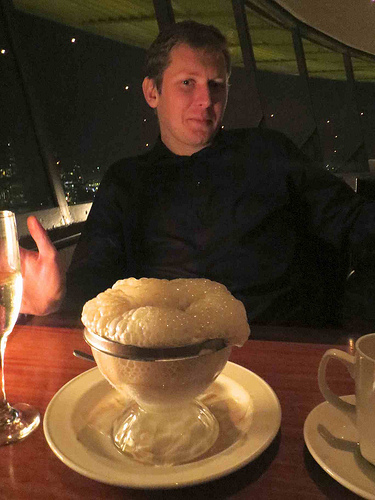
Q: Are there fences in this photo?
A: No, there are no fences.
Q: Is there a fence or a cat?
A: No, there are no fences or cats.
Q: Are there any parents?
A: No, there are no parents.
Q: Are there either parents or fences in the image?
A: No, there are no parents or fences.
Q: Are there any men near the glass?
A: Yes, there is a man near the glass.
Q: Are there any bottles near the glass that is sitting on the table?
A: No, there is a man near the glass.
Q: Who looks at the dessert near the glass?
A: The man looks at the dessert.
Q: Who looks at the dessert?
A: The man looks at the dessert.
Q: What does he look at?
A: The man looks at the dessert.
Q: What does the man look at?
A: The man looks at the dessert.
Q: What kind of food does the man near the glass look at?
A: The man looks at the dessert.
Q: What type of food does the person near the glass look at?
A: The man looks at the dessert.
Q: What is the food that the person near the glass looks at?
A: The food is a dessert.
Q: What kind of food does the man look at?
A: The man looks at the dessert.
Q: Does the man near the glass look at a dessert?
A: Yes, the man looks at a dessert.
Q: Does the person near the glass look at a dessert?
A: Yes, the man looks at a dessert.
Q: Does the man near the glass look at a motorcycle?
A: No, the man looks at a dessert.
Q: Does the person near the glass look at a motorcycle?
A: No, the man looks at a dessert.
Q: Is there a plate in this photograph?
A: Yes, there is a plate.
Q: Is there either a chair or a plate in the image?
A: Yes, there is a plate.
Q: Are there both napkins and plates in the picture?
A: No, there is a plate but no napkins.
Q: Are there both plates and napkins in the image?
A: No, there is a plate but no napkins.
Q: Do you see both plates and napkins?
A: No, there is a plate but no napkins.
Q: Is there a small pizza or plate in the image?
A: Yes, there is a small plate.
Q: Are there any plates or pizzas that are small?
A: Yes, the plate is small.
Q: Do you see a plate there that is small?
A: Yes, there is a small plate.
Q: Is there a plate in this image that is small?
A: Yes, there is a plate that is small.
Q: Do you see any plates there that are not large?
A: Yes, there is a small plate.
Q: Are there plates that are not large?
A: Yes, there is a small plate.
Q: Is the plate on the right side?
A: Yes, the plate is on the right of the image.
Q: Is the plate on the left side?
A: No, the plate is on the right of the image.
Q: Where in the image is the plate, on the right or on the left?
A: The plate is on the right of the image.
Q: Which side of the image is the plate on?
A: The plate is on the right of the image.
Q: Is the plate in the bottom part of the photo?
A: Yes, the plate is in the bottom of the image.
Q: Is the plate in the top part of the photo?
A: No, the plate is in the bottom of the image.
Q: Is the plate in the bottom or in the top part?
A: The plate is in the bottom of the image.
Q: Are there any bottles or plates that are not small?
A: No, there is a plate but it is small.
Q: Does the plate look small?
A: Yes, the plate is small.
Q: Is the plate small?
A: Yes, the plate is small.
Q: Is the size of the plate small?
A: Yes, the plate is small.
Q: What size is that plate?
A: The plate is small.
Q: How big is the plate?
A: The plate is small.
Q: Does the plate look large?
A: No, the plate is small.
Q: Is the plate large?
A: No, the plate is small.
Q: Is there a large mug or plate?
A: No, there is a plate but it is small.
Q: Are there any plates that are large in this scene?
A: No, there is a plate but it is small.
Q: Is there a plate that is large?
A: No, there is a plate but it is small.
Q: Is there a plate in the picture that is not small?
A: No, there is a plate but it is small.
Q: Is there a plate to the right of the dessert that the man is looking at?
A: Yes, there is a plate to the right of the dessert.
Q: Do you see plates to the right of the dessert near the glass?
A: Yes, there is a plate to the right of the dessert.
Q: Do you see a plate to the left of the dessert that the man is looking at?
A: No, the plate is to the right of the dessert.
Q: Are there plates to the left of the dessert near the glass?
A: No, the plate is to the right of the dessert.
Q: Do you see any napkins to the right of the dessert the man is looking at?
A: No, there is a plate to the right of the dessert.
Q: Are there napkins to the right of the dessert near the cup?
A: No, there is a plate to the right of the dessert.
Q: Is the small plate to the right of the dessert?
A: Yes, the plate is to the right of the dessert.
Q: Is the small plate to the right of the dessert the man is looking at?
A: Yes, the plate is to the right of the dessert.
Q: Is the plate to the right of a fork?
A: No, the plate is to the right of the dessert.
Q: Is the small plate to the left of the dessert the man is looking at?
A: No, the plate is to the right of the dessert.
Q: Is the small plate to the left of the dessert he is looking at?
A: No, the plate is to the right of the dessert.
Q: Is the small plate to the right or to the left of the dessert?
A: The plate is to the right of the dessert.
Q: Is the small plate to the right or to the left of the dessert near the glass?
A: The plate is to the right of the dessert.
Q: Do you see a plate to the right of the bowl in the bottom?
A: Yes, there is a plate to the right of the bowl.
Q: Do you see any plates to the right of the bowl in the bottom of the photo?
A: Yes, there is a plate to the right of the bowl.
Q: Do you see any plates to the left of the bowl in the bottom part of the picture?
A: No, the plate is to the right of the bowl.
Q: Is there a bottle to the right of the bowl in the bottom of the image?
A: No, there is a plate to the right of the bowl.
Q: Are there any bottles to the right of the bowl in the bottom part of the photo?
A: No, there is a plate to the right of the bowl.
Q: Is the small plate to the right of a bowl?
A: Yes, the plate is to the right of a bowl.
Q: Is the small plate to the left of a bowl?
A: No, the plate is to the right of a bowl.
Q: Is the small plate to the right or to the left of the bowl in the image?
A: The plate is to the right of the bowl.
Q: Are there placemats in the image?
A: No, there are no placemats.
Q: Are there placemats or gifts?
A: No, there are no placemats or gifts.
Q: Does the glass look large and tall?
A: Yes, the glass is large and tall.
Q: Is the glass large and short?
A: No, the glass is large but tall.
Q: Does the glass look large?
A: Yes, the glass is large.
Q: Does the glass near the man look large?
A: Yes, the glass is large.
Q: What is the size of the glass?
A: The glass is large.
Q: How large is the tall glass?
A: The glass is large.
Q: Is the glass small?
A: No, the glass is large.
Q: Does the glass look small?
A: No, the glass is large.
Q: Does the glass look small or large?
A: The glass is large.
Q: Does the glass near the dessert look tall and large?
A: Yes, the glass is tall and large.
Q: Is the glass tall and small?
A: No, the glass is tall but large.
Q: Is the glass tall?
A: Yes, the glass is tall.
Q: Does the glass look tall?
A: Yes, the glass is tall.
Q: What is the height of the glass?
A: The glass is tall.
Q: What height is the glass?
A: The glass is tall.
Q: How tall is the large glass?
A: The glass is tall.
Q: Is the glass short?
A: No, the glass is tall.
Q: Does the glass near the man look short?
A: No, the glass is tall.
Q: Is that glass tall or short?
A: The glass is tall.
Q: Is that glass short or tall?
A: The glass is tall.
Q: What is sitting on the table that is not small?
A: The glass is sitting on the table.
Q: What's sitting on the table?
A: The glass is sitting on the table.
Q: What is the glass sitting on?
A: The glass is sitting on the table.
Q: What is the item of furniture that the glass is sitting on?
A: The piece of furniture is a table.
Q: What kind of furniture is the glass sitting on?
A: The glass is sitting on the table.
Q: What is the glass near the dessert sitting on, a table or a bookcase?
A: The glass is sitting on a table.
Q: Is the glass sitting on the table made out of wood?
A: Yes, the glass is sitting on the table.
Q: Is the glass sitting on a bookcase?
A: No, the glass is sitting on the table.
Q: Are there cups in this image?
A: Yes, there is a cup.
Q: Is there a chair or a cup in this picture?
A: Yes, there is a cup.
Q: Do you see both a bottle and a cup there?
A: No, there is a cup but no bottles.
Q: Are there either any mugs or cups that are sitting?
A: Yes, the cup is sitting.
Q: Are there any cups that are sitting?
A: Yes, there is a cup that is sitting.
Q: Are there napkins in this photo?
A: No, there are no napkins.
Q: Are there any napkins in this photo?
A: No, there are no napkins.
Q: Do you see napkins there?
A: No, there are no napkins.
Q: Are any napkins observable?
A: No, there are no napkins.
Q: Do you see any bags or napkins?
A: No, there are no napkins or bags.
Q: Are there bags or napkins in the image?
A: No, there are no napkins or bags.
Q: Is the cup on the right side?
A: Yes, the cup is on the right of the image.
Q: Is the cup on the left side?
A: No, the cup is on the right of the image.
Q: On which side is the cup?
A: The cup is on the right of the image.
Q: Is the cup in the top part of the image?
A: No, the cup is in the bottom of the image.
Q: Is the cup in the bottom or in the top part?
A: The cup is in the bottom of the image.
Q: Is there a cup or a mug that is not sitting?
A: No, there is a cup but it is sitting.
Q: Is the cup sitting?
A: Yes, the cup is sitting.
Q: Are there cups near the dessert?
A: Yes, there is a cup near the dessert.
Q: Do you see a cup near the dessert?
A: Yes, there is a cup near the dessert.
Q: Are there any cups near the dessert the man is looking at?
A: Yes, there is a cup near the dessert.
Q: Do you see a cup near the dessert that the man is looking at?
A: Yes, there is a cup near the dessert.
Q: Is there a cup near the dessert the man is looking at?
A: Yes, there is a cup near the dessert.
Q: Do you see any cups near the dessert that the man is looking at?
A: Yes, there is a cup near the dessert.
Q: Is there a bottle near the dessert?
A: No, there is a cup near the dessert.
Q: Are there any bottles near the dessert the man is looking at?
A: No, there is a cup near the dessert.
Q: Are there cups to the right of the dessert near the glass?
A: Yes, there is a cup to the right of the dessert.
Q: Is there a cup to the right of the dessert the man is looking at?
A: Yes, there is a cup to the right of the dessert.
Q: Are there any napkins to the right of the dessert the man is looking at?
A: No, there is a cup to the right of the dessert.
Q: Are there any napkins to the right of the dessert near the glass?
A: No, there is a cup to the right of the dessert.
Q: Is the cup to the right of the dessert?
A: Yes, the cup is to the right of the dessert.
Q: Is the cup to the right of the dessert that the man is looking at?
A: Yes, the cup is to the right of the dessert.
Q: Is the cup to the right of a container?
A: No, the cup is to the right of the dessert.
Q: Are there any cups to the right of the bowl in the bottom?
A: Yes, there is a cup to the right of the bowl.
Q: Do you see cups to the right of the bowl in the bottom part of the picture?
A: Yes, there is a cup to the right of the bowl.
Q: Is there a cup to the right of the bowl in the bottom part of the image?
A: Yes, there is a cup to the right of the bowl.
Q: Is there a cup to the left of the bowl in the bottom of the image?
A: No, the cup is to the right of the bowl.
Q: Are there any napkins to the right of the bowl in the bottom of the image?
A: No, there is a cup to the right of the bowl.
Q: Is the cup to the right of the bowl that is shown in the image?
A: Yes, the cup is to the right of the bowl.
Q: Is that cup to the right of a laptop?
A: No, the cup is to the right of the bowl.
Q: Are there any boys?
A: No, there are no boys.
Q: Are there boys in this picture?
A: No, there are no boys.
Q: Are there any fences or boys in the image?
A: No, there are no boys or fences.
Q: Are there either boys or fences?
A: No, there are no boys or fences.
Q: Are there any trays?
A: No, there are no trays.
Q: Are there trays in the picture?
A: No, there are no trays.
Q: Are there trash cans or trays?
A: No, there are no trays or trash cans.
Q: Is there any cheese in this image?
A: No, there is no cheese.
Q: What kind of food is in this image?
A: The food is a dessert.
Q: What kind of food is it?
A: The food is a dessert.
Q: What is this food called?
A: This is a dessert.